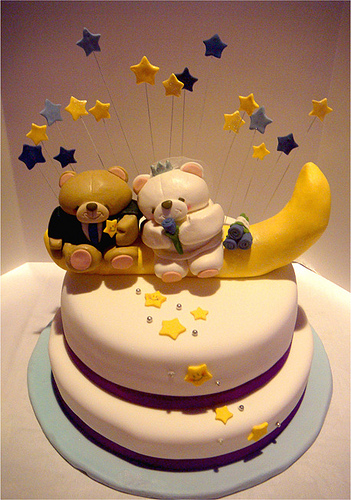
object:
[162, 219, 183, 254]
holder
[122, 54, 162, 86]
star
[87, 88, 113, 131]
star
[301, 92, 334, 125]
star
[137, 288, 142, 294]
metal dot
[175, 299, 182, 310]
metal dot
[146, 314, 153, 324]
metal dot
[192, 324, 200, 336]
metal dot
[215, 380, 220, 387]
metal dot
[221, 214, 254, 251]
flower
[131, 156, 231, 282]
bear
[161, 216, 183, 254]
flower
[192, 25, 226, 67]
star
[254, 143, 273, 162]
star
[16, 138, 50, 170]
stars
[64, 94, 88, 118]
yellow star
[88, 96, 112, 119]
yellow star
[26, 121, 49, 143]
yellow star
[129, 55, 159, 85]
yellow star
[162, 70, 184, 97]
yellow star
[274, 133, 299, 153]
star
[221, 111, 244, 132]
star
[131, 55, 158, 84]
star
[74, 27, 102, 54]
star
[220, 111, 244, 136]
star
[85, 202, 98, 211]
nose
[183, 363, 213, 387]
face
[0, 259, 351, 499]
tablecloth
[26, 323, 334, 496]
plate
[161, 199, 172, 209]
brown nose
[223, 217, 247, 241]
towel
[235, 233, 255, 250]
towel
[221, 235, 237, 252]
towel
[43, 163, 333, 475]
cake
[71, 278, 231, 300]
shadow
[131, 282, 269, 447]
star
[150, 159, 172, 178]
blue crown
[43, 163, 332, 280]
moon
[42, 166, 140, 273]
bear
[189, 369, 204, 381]
smiling face